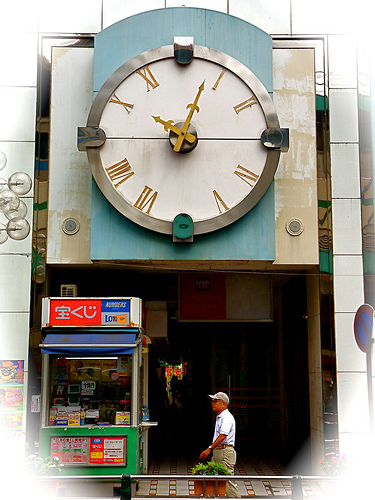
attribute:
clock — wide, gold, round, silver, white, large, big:
[77, 36, 292, 245]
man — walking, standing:
[200, 390, 240, 475]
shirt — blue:
[211, 406, 238, 446]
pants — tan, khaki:
[210, 447, 241, 497]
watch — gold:
[206, 444, 214, 452]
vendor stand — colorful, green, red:
[34, 294, 161, 473]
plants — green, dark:
[192, 462, 230, 497]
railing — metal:
[28, 471, 370, 494]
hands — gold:
[148, 77, 212, 154]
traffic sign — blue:
[347, 304, 373, 353]